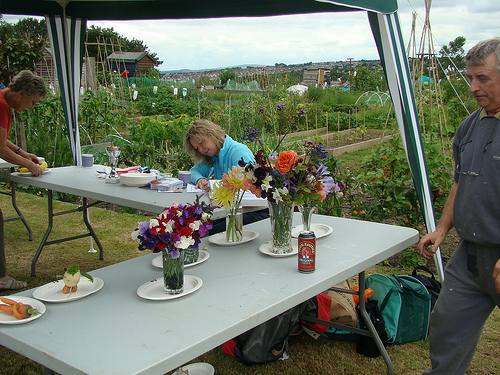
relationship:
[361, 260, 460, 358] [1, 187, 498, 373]
bag on grass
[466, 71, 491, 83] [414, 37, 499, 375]
eye of a man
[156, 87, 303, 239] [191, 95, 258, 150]
lady with hair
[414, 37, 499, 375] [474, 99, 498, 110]
man has chin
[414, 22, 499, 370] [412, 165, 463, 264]
man has arm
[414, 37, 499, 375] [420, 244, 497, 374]
man has leg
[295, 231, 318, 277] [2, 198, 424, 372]
can on table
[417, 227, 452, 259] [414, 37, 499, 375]
hand of a man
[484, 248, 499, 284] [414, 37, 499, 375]
hand of a man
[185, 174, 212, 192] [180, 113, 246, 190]
hand of a man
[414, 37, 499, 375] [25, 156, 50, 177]
man of a hand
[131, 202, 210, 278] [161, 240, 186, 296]
flowers in a vase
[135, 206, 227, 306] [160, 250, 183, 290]
flowers in a vase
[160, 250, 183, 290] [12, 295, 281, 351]
vase on the table